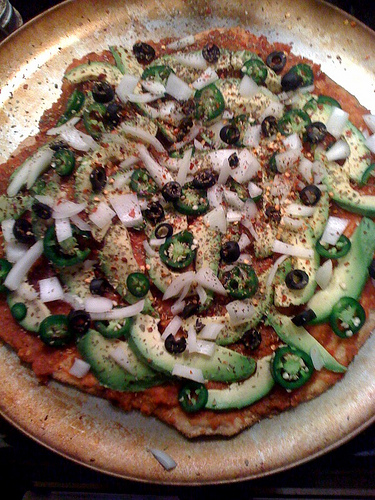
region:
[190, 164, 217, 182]
topping on the pizza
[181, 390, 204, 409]
topping on the pizza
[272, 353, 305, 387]
topping on the pizza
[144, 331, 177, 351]
topping on the pizza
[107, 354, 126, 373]
topping on the pizza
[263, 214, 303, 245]
topping on the pizza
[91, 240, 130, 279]
topping on the pizza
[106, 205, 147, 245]
topping on the pizza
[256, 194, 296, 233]
topping on the pizza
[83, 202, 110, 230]
topping on the pizza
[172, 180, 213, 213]
jalapeno on a pizza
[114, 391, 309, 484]
crust of a pizza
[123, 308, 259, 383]
avocado on pizza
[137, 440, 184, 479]
small piece of onion on crust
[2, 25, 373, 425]
a combination pizza with onions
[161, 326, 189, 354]
olives on a pizza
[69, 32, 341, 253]
bunch of olives on a pizza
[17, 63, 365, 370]
bunch of onions on a pizza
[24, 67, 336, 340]
pizza with a lot of chili sauce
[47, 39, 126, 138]
red sauce and avocados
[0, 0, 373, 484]
a pizza on a large round plate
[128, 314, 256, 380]
a thin slice of avocado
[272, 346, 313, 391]
a thin slice of jalapeno pepper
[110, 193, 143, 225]
a small piece of onion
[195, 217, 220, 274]
red pepper flakes sprinkled on a pizza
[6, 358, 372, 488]
the bottom of a large plate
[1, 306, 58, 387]
tomato sauce on the edge of a pizza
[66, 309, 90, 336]
a small black olive slice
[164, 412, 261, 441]
the thin crust of a homemade pizza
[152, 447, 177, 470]
a sliver on white onion on the plate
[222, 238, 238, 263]
the olive slice on the pizza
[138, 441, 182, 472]
an onion slice on the crust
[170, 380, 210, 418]
the jaleeno slice on the pizza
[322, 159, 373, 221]
the slice of avacado on the pizza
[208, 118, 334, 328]
the seasoning on the pizza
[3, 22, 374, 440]
the flatbread pizza on the pizza tray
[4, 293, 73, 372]
the pizza suace under the veggies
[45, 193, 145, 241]
a pile of onions slices on top of the pizza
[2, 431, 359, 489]
the trey for the pizza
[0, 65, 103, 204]
the crust misshapen on the pizza